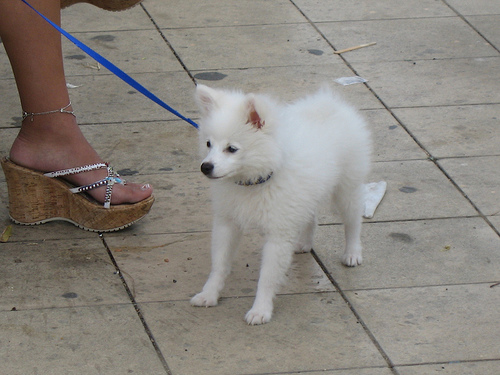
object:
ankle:
[35, 111, 66, 136]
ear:
[234, 92, 271, 132]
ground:
[0, 0, 499, 374]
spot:
[191, 69, 227, 82]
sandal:
[0, 153, 156, 233]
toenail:
[140, 183, 151, 189]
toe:
[129, 181, 152, 202]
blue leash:
[24, 0, 203, 133]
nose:
[199, 159, 215, 176]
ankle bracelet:
[17, 101, 78, 124]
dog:
[186, 83, 368, 326]